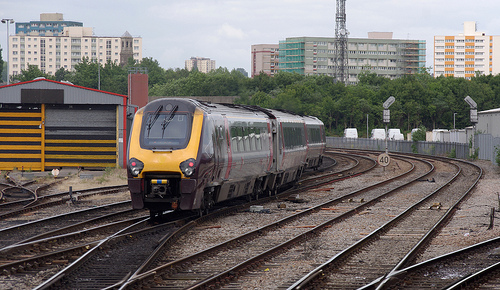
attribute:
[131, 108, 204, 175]
paint — yellow